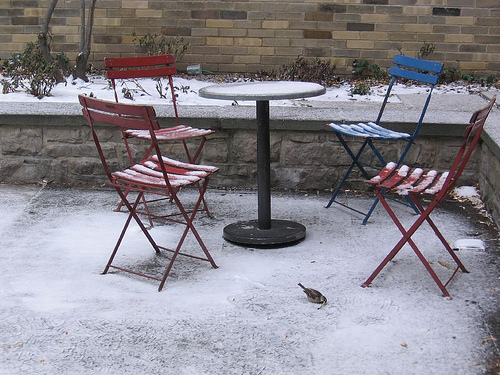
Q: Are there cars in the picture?
A: No, there are no cars.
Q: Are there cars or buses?
A: No, there are no cars or buses.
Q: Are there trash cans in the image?
A: No, there are no trash cans.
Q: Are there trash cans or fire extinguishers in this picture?
A: No, there are no trash cans or fire extinguishers.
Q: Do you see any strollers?
A: No, there are no strollers.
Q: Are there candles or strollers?
A: No, there are no strollers or candles.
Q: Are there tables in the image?
A: Yes, there is a table.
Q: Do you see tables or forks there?
A: Yes, there is a table.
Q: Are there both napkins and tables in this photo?
A: No, there is a table but no napkins.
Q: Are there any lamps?
A: No, there are no lamps.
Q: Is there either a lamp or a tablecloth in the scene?
A: No, there are no lamps or tablecloths.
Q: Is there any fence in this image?
A: No, there are no fences.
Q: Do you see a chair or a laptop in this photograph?
A: Yes, there is a chair.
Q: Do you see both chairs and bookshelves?
A: No, there is a chair but no bookshelves.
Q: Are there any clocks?
A: No, there are no clocks.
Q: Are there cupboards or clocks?
A: No, there are no clocks or cupboards.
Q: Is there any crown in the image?
A: No, there are no crowns.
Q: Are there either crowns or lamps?
A: No, there are no crowns or lamps.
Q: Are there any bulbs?
A: No, there are no bulbs.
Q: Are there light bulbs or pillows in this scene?
A: No, there are no light bulbs or pillows.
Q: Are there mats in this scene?
A: No, there are no mats.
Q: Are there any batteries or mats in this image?
A: No, there are no mats or batteries.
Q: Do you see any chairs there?
A: Yes, there is a chair.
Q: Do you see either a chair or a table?
A: Yes, there is a chair.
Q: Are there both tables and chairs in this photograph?
A: Yes, there are both a chair and a table.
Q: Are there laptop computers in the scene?
A: No, there are no laptop computers.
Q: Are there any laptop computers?
A: No, there are no laptop computers.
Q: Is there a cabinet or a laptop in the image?
A: No, there are no laptops or cabinets.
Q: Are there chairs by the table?
A: Yes, there is a chair by the table.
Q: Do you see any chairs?
A: Yes, there is a chair.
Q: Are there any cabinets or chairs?
A: Yes, there is a chair.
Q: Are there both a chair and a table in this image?
A: Yes, there are both a chair and a table.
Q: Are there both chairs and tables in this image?
A: Yes, there are both a chair and a table.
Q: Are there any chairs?
A: Yes, there is a chair.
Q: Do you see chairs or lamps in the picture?
A: Yes, there is a chair.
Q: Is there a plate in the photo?
A: No, there are no plates.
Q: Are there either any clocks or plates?
A: No, there are no plates or clocks.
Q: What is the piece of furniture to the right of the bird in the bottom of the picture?
A: The piece of furniture is a chair.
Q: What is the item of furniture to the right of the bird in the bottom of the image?
A: The piece of furniture is a chair.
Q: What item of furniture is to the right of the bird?
A: The piece of furniture is a chair.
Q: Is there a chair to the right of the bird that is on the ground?
A: Yes, there is a chair to the right of the bird.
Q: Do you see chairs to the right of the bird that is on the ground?
A: Yes, there is a chair to the right of the bird.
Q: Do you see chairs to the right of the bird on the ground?
A: Yes, there is a chair to the right of the bird.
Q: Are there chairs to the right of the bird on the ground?
A: Yes, there is a chair to the right of the bird.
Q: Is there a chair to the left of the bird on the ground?
A: No, the chair is to the right of the bird.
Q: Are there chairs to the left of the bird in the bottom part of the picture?
A: No, the chair is to the right of the bird.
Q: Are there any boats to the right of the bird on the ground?
A: No, there is a chair to the right of the bird.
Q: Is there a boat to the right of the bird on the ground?
A: No, there is a chair to the right of the bird.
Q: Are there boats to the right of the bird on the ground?
A: No, there is a chair to the right of the bird.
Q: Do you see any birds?
A: Yes, there is a bird.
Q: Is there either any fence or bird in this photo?
A: Yes, there is a bird.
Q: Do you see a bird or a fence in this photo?
A: Yes, there is a bird.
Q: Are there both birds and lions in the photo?
A: No, there is a bird but no lions.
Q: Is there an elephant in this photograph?
A: No, there are no elephants.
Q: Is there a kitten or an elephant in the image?
A: No, there are no elephants or kittens.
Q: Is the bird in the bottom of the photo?
A: Yes, the bird is in the bottom of the image.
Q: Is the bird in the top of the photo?
A: No, the bird is in the bottom of the image.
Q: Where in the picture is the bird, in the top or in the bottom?
A: The bird is in the bottom of the image.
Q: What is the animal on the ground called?
A: The animal is a bird.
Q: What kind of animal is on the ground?
A: The animal is a bird.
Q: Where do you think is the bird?
A: The bird is on the ground.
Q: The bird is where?
A: The bird is on the ground.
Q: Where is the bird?
A: The bird is on the ground.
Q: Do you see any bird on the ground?
A: Yes, there is a bird on the ground.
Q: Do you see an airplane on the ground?
A: No, there is a bird on the ground.